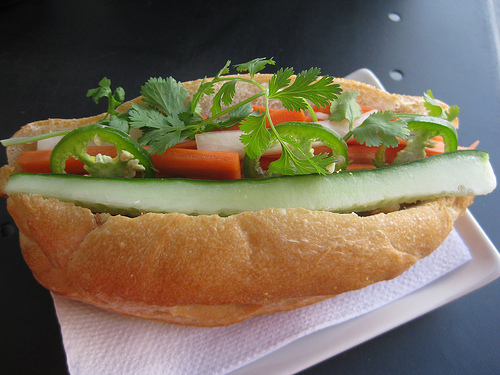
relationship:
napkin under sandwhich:
[50, 208, 499, 375] [0, 56, 499, 328]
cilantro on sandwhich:
[0, 56, 460, 174] [0, 56, 499, 328]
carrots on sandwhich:
[18, 103, 480, 178] [0, 56, 499, 328]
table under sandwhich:
[0, 0, 498, 374] [0, 56, 499, 328]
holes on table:
[389, 10, 404, 83] [0, 0, 498, 374]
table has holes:
[0, 0, 498, 374] [389, 10, 404, 83]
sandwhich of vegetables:
[0, 56, 499, 328] [2, 60, 497, 215]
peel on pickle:
[7, 148, 488, 184] [3, 151, 498, 212]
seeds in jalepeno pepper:
[97, 150, 145, 177] [48, 124, 155, 180]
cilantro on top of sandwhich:
[0, 56, 460, 174] [0, 56, 499, 328]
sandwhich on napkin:
[0, 56, 499, 328] [50, 208, 499, 375]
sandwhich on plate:
[0, 56, 499, 328] [229, 206, 499, 373]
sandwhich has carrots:
[0, 56, 499, 328] [18, 103, 480, 178]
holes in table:
[389, 10, 404, 83] [0, 0, 498, 374]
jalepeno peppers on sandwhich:
[48, 121, 459, 177] [0, 56, 499, 328]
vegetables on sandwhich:
[2, 60, 497, 215] [0, 56, 499, 328]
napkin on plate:
[50, 208, 499, 375] [229, 206, 499, 373]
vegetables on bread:
[2, 60, 497, 215] [7, 72, 475, 325]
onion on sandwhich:
[195, 109, 378, 159] [0, 56, 499, 328]